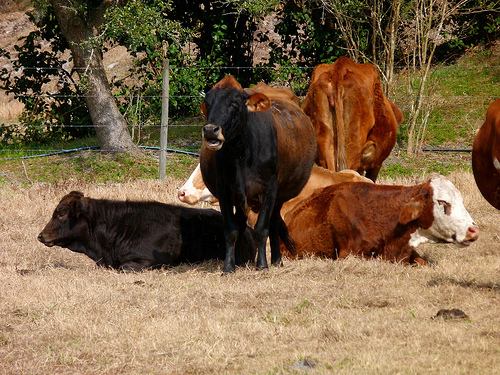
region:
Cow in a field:
[305, 152, 473, 294]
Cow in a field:
[37, 190, 236, 289]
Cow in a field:
[188, 91, 313, 254]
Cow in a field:
[298, 48, 404, 223]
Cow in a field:
[29, 170, 245, 287]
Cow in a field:
[292, 145, 497, 312]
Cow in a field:
[186, 68, 343, 242]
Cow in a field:
[194, 51, 483, 271]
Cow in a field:
[13, 175, 470, 297]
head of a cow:
[176, 71, 268, 152]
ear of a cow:
[252, 89, 283, 104]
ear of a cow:
[190, 91, 210, 126]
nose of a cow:
[202, 119, 233, 137]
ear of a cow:
[71, 187, 104, 204]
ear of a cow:
[392, 192, 442, 233]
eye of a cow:
[435, 197, 470, 214]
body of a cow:
[281, 165, 417, 251]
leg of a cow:
[199, 202, 250, 267]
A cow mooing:
[201, 121, 226, 151]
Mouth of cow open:
[206, 139, 218, 146]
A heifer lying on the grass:
[35, 190, 175, 272]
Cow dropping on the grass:
[437, 310, 462, 320]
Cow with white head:
[434, 181, 476, 253]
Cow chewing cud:
[463, 237, 471, 244]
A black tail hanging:
[283, 235, 289, 246]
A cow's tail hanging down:
[337, 115, 342, 167]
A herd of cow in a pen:
[28, 46, 490, 300]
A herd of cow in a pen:
[30, 48, 487, 288]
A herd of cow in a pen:
[33, 48, 496, 274]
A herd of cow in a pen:
[31, 53, 484, 289]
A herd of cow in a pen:
[34, 47, 484, 292]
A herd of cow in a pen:
[30, 53, 483, 278]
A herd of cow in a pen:
[33, 50, 480, 292]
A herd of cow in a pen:
[31, 48, 488, 278]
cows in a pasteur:
[26, 24, 497, 335]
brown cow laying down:
[309, 146, 479, 303]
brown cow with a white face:
[299, 125, 489, 290]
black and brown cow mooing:
[183, 46, 380, 253]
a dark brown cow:
[35, 160, 283, 320]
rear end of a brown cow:
[305, 37, 472, 224]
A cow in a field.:
[277, 177, 480, 263]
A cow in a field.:
[201, 76, 314, 270]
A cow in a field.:
[179, 159, 221, 206]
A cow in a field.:
[36, 190, 260, 267]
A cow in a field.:
[302, 56, 402, 182]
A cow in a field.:
[471, 97, 499, 214]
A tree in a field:
[31, 1, 151, 161]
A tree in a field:
[405, 0, 475, 158]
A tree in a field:
[324, 0, 402, 100]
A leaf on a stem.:
[45, 102, 49, 107]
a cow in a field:
[48, 174, 259, 266]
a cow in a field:
[205, 79, 317, 258]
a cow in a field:
[291, 161, 475, 271]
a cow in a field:
[311, 49, 401, 186]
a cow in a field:
[174, 156, 366, 212]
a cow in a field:
[450, 86, 498, 209]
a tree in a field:
[11, 6, 206, 146]